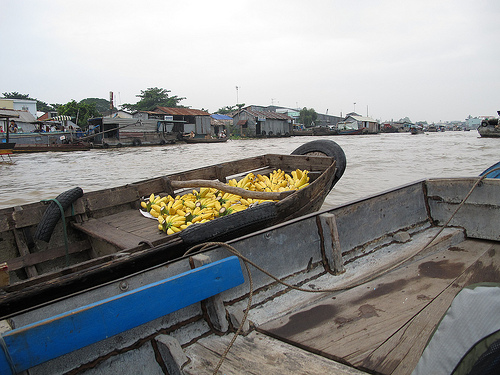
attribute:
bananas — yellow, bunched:
[141, 165, 315, 246]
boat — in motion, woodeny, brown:
[1, 151, 349, 329]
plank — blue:
[10, 250, 244, 367]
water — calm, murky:
[343, 133, 435, 172]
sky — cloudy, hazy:
[72, 0, 497, 103]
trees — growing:
[54, 83, 205, 116]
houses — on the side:
[8, 107, 291, 147]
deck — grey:
[339, 233, 497, 309]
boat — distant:
[410, 123, 428, 136]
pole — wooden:
[168, 177, 291, 207]